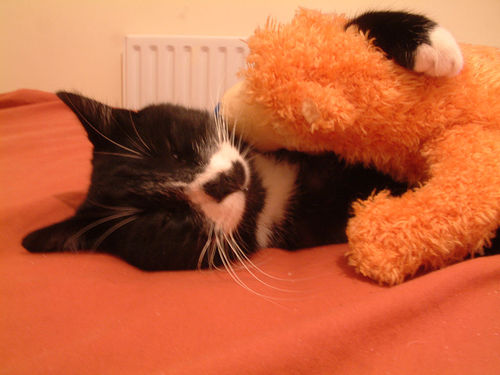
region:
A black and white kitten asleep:
[21, 6, 498, 254]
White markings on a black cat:
[184, 136, 297, 244]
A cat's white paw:
[402, 22, 464, 74]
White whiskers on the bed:
[199, 229, 302, 301]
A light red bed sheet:
[0, 84, 498, 372]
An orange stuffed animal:
[214, 24, 496, 287]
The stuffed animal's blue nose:
[210, 102, 230, 122]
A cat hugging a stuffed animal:
[21, 16, 498, 264]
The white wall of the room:
[0, 2, 497, 99]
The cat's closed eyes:
[144, 134, 190, 238]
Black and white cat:
[22, 6, 496, 302]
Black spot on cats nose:
[207, 129, 254, 246]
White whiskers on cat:
[160, 92, 287, 320]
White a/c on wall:
[114, 31, 271, 116]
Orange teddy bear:
[205, 1, 499, 261]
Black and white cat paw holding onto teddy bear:
[268, 4, 483, 161]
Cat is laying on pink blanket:
[4, 86, 497, 371]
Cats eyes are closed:
[126, 114, 203, 271]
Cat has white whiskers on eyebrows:
[82, 103, 175, 248]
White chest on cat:
[229, 128, 306, 253]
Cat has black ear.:
[63, 94, 140, 149]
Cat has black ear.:
[18, 208, 106, 243]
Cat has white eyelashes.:
[95, 94, 127, 244]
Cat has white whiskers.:
[206, 118, 251, 340]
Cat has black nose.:
[203, 165, 225, 182]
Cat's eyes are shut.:
[145, 138, 221, 264]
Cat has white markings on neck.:
[258, 162, 309, 233]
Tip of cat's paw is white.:
[419, 31, 439, 54]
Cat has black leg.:
[358, 4, 403, 54]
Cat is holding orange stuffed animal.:
[349, 5, 409, 188]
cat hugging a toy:
[36, 28, 471, 290]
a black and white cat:
[55, 69, 280, 256]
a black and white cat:
[58, 79, 330, 363]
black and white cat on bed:
[57, 78, 349, 260]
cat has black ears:
[32, 78, 171, 266]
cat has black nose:
[214, 156, 249, 217]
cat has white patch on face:
[188, 137, 254, 235]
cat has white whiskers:
[181, 122, 288, 312]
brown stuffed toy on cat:
[246, 31, 498, 224]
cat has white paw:
[402, 26, 452, 83]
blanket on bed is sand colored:
[6, 96, 483, 369]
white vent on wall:
[120, 34, 233, 126]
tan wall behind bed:
[4, 13, 120, 95]